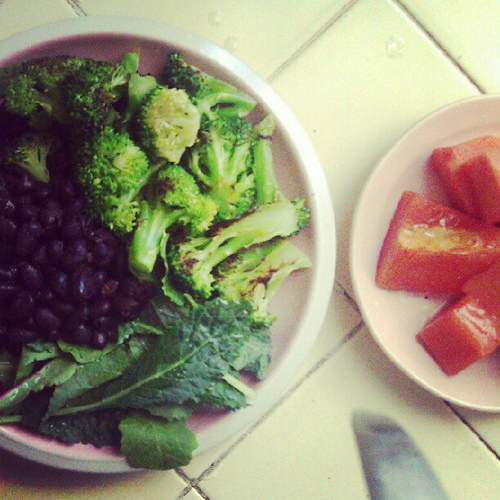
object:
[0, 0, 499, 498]
counter top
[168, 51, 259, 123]
broccoli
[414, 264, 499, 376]
food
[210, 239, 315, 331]
food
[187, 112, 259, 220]
food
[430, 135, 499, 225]
food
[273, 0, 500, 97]
ground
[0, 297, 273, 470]
green leaf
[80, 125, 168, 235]
broccoli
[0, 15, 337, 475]
bowl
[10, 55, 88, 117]
food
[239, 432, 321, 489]
tile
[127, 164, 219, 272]
broccoli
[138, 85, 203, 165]
broccoli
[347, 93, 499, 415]
bowl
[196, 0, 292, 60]
tile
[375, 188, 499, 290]
food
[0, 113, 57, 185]
food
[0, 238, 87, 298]
food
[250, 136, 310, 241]
food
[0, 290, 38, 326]
beans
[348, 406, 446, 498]
knife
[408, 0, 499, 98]
tiles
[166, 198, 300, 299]
food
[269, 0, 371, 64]
grout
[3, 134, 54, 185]
food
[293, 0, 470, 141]
tile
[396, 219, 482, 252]
blob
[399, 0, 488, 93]
grout